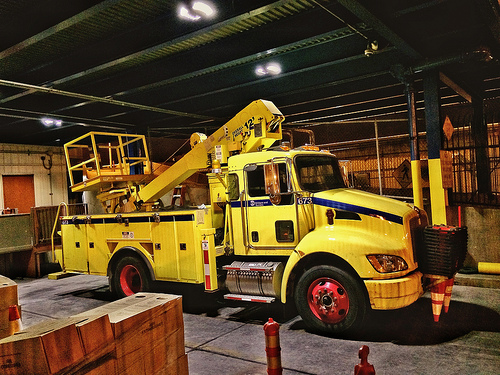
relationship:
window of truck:
[248, 168, 286, 191] [52, 142, 407, 313]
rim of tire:
[314, 287, 347, 321] [281, 263, 362, 339]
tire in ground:
[281, 263, 362, 339] [40, 271, 486, 365]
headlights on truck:
[366, 252, 409, 273] [52, 142, 407, 313]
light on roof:
[177, 1, 223, 21] [12, 10, 497, 130]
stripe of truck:
[64, 215, 206, 227] [52, 142, 407, 313]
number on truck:
[299, 200, 318, 207] [52, 142, 407, 313]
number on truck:
[243, 116, 254, 130] [52, 142, 407, 313]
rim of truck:
[314, 287, 347, 321] [52, 142, 407, 313]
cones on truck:
[427, 278, 454, 313] [52, 142, 407, 313]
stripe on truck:
[64, 215, 206, 227] [52, 142, 407, 313]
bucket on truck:
[74, 163, 134, 208] [52, 142, 407, 313]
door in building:
[5, 173, 42, 217] [6, 10, 497, 250]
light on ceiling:
[177, 1, 223, 21] [24, 7, 487, 139]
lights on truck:
[280, 139, 338, 156] [52, 142, 407, 313]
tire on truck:
[293, 263, 366, 335] [52, 142, 407, 313]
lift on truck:
[75, 122, 213, 196] [52, 142, 407, 313]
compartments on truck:
[55, 215, 192, 274] [52, 142, 407, 313]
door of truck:
[238, 163, 294, 246] [52, 142, 407, 313]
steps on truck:
[210, 253, 285, 311] [52, 142, 407, 313]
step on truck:
[39, 227, 65, 275] [52, 142, 407, 313]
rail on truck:
[50, 197, 67, 239] [52, 142, 407, 313]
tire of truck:
[107, 250, 158, 308] [52, 142, 407, 313]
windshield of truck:
[295, 155, 348, 191] [52, 142, 407, 313]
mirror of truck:
[274, 157, 294, 201] [52, 142, 407, 313]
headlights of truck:
[366, 252, 405, 269] [52, 142, 407, 313]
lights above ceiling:
[173, 2, 298, 90] [24, 7, 487, 139]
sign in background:
[437, 103, 464, 140] [6, 5, 456, 178]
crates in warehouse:
[10, 297, 188, 374] [8, 13, 492, 369]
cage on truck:
[58, 128, 149, 187] [52, 142, 407, 313]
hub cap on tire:
[115, 262, 142, 295] [107, 250, 153, 307]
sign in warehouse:
[437, 103, 464, 140] [8, 13, 492, 369]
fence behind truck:
[27, 199, 93, 250] [52, 142, 407, 313]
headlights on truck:
[366, 252, 405, 269] [52, 142, 407, 313]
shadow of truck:
[367, 293, 491, 355] [52, 142, 407, 313]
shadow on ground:
[367, 293, 491, 355] [40, 271, 486, 365]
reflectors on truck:
[199, 246, 222, 296] [52, 142, 407, 313]